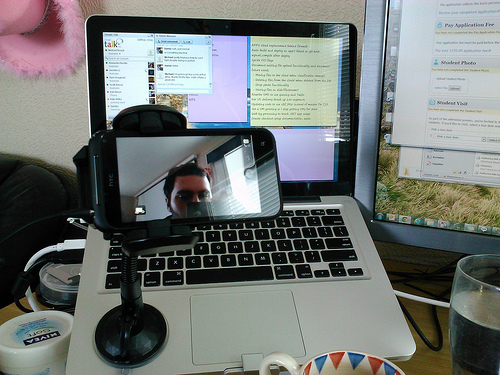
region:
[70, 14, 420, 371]
A laptop computer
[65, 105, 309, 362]
A mobile phone mounted to the computer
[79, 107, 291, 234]
A mobile phone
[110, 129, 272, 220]
The screen on a mobile phone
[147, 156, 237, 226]
A man's face on the mobile phone screen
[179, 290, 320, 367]
The touchpad on a computer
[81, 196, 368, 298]
The keyboard on a computer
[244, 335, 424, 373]
A portion of a colorful mug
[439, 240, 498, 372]
A portion of a glass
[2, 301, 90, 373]
A container of Nivea cream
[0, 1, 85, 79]
A pink hat is on the wall.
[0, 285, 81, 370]
A container of lotion.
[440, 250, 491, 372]
A glass of water.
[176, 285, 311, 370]
The laptop's trackpad.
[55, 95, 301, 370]
The phone is attached to a stand.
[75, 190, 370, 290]
The keyboard.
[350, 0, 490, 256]
A large monitor.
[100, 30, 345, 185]
Programs are open on the laptop screen.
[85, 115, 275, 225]
The smartphone is black.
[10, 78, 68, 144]
The wall is white.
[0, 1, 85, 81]
Partial view of a pink fuzzy hat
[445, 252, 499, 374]
Almost full glass of water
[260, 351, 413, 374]
Edge of triangle decorated mug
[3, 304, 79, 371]
Tub of Nivea lotion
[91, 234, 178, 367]
Cell phone stand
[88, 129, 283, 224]
HTC smartphone in horizontal layout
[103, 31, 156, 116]
Google talk contact list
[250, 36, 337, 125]
Windows sticky note list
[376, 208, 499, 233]
Program icons in Windows taskbar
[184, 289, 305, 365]
Track pad for laptop mouse movement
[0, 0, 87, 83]
a pink hat on the wall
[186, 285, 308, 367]
a gray touch pad on the computer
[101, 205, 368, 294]
a black computer keyboard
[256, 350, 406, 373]
a red, white, and blue mug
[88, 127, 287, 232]
a cell phone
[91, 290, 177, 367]
the base of a phone stand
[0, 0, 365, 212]
a white plaster wall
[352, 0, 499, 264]
a black computer monitor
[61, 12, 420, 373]
a black and gray laptop computer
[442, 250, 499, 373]
a drinking glass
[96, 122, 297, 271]
This is a smartphone that this man has attached to his computer.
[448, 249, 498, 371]
There is a glass of still water next to the computer.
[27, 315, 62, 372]
There is a container of handcream to the left.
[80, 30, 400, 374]
There is a laptop on the desk and the laptop is white.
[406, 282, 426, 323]
The charging cord connected to the laptop is white.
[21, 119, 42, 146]
The wall has a cream color and has texture.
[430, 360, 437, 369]
There is a light brown color on the desk.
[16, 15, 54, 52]
There is a pink hat on the wall of the office.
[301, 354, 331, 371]
There is a red, white, and blue coffee cup.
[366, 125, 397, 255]
The frame of the screen is black and is shiny.